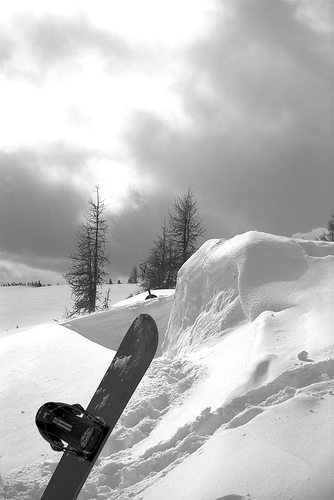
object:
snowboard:
[33, 309, 162, 500]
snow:
[0, 223, 334, 500]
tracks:
[5, 354, 334, 500]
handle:
[139, 262, 146, 273]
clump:
[296, 349, 313, 362]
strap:
[36, 397, 107, 463]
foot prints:
[248, 356, 269, 383]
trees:
[62, 183, 110, 320]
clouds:
[0, 0, 334, 286]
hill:
[162, 230, 334, 347]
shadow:
[56, 289, 175, 359]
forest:
[0, 267, 148, 287]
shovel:
[144, 287, 157, 298]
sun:
[0, 0, 239, 216]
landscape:
[0, 0, 333, 500]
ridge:
[0, 224, 333, 324]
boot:
[31, 397, 111, 465]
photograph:
[0, 0, 334, 498]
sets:
[0, 335, 334, 499]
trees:
[109, 277, 115, 285]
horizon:
[0, 228, 332, 293]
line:
[0, 280, 174, 289]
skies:
[0, 0, 331, 272]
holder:
[34, 390, 107, 461]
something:
[32, 308, 166, 500]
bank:
[0, 226, 334, 499]